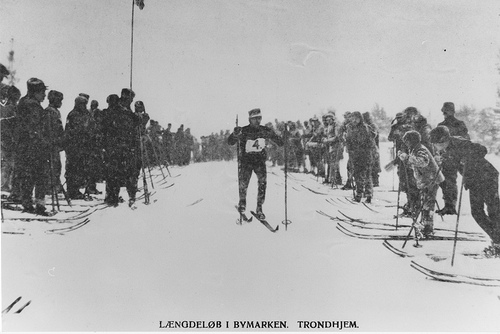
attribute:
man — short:
[234, 106, 280, 226]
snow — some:
[186, 233, 352, 303]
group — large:
[11, 70, 161, 223]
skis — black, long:
[334, 210, 479, 244]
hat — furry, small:
[245, 106, 261, 118]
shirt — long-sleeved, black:
[233, 126, 283, 162]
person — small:
[229, 106, 284, 226]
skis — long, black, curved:
[233, 206, 291, 236]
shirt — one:
[229, 124, 280, 161]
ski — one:
[254, 208, 281, 235]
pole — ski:
[226, 112, 272, 235]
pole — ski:
[272, 121, 302, 240]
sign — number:
[240, 130, 271, 158]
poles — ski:
[231, 121, 301, 235]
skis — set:
[229, 132, 302, 240]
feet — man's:
[225, 199, 270, 217]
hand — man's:
[277, 124, 299, 150]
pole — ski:
[269, 105, 310, 239]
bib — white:
[239, 132, 269, 164]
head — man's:
[242, 109, 279, 137]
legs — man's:
[241, 160, 278, 223]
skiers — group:
[0, 56, 181, 251]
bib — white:
[243, 139, 265, 152]